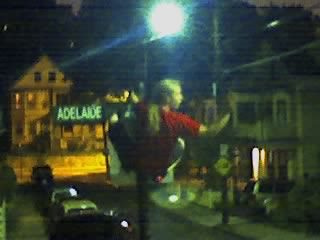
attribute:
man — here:
[106, 79, 231, 179]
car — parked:
[44, 211, 130, 240]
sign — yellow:
[215, 157, 233, 176]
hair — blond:
[143, 80, 184, 138]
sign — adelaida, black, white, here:
[57, 107, 104, 120]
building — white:
[8, 54, 78, 156]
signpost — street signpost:
[221, 172, 229, 222]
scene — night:
[0, 1, 318, 239]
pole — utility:
[99, 74, 111, 182]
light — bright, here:
[140, 1, 198, 43]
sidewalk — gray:
[152, 188, 320, 240]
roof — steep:
[8, 51, 44, 90]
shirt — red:
[121, 103, 202, 166]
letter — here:
[57, 108, 63, 121]